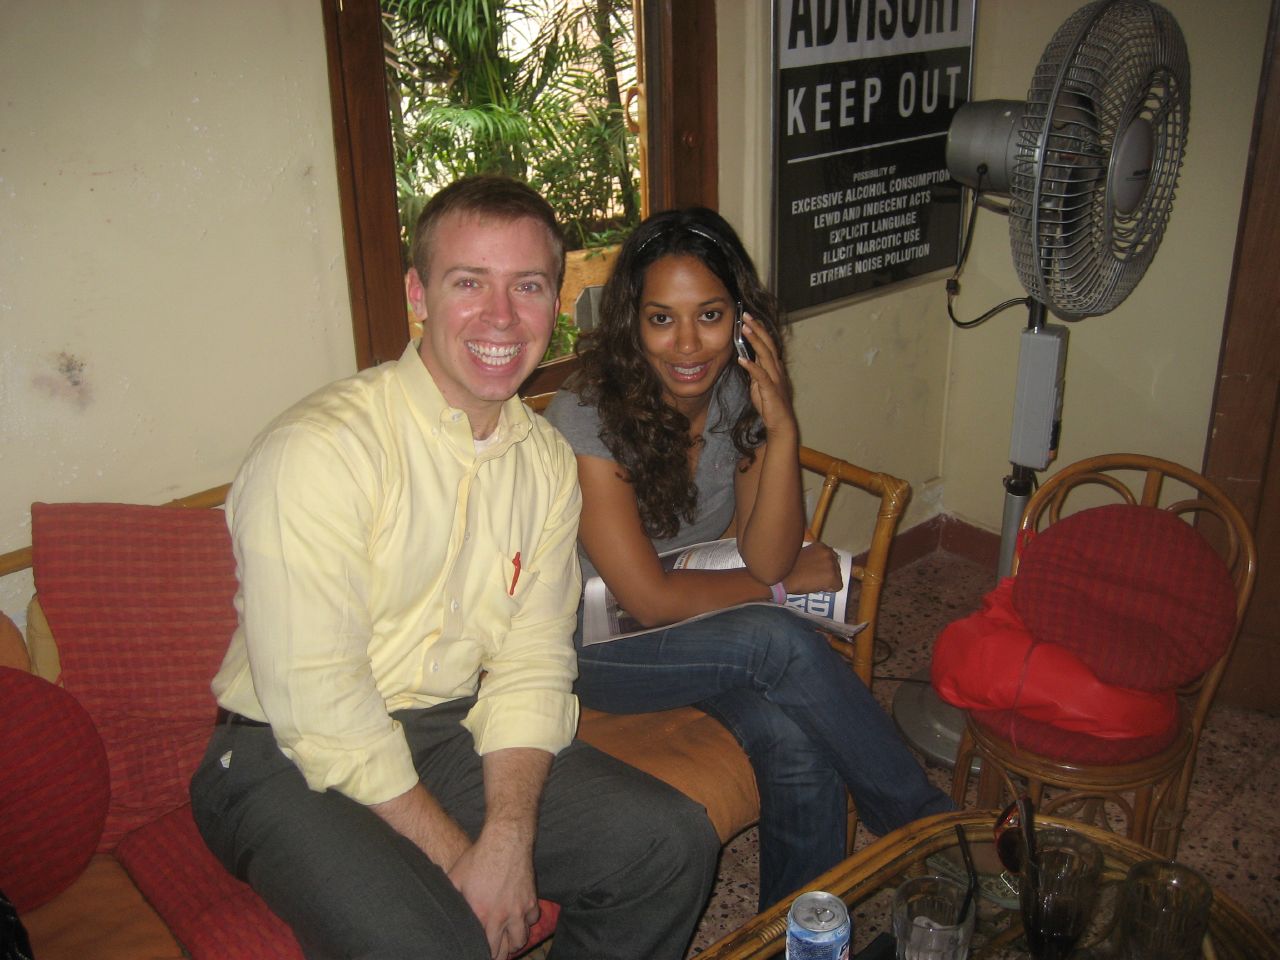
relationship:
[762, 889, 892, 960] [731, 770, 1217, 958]
drink on table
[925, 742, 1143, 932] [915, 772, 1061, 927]
tumblers with straws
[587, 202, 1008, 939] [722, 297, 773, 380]
female holding phone